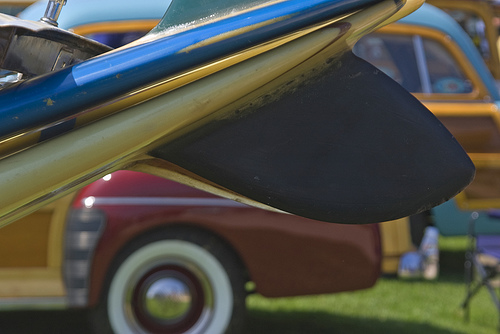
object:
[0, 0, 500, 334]
car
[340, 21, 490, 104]
window frame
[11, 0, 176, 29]
roof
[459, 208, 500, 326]
chair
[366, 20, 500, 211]
door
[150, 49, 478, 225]
fin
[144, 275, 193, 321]
hubcap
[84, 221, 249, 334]
tire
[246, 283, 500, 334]
grass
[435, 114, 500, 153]
panel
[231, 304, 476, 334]
shadow